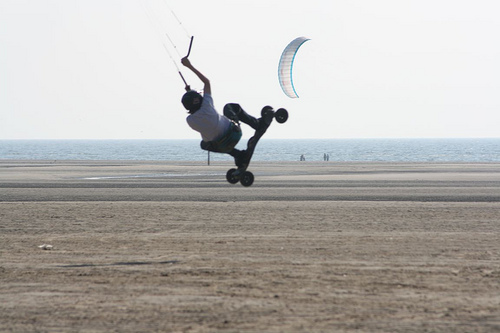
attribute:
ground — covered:
[53, 191, 374, 285]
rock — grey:
[33, 228, 59, 263]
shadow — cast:
[65, 239, 155, 287]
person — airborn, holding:
[157, 37, 277, 184]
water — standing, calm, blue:
[355, 130, 468, 153]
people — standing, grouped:
[286, 143, 381, 188]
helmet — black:
[175, 80, 208, 102]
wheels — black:
[200, 170, 300, 198]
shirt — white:
[176, 102, 226, 132]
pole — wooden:
[168, 24, 218, 67]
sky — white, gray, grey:
[362, 19, 498, 77]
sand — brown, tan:
[346, 213, 475, 267]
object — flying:
[277, 38, 338, 60]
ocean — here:
[289, 114, 493, 176]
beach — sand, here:
[227, 175, 498, 295]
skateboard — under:
[233, 102, 270, 163]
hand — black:
[176, 77, 196, 94]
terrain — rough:
[141, 271, 242, 317]